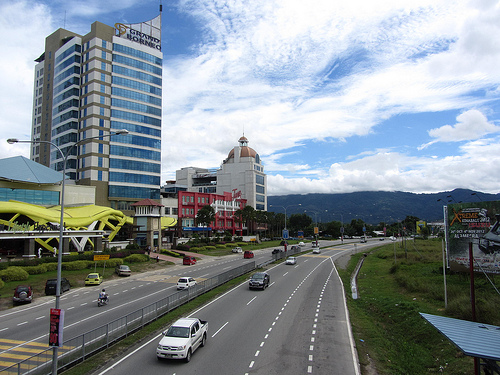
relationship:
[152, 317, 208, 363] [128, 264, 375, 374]
truck in road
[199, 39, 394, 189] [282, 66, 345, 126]
sky has clouds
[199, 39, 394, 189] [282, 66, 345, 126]
sky as clouds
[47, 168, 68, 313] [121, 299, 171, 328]
pole beside fence